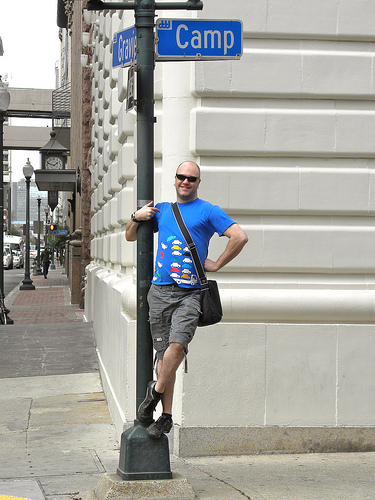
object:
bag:
[170, 202, 224, 328]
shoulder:
[192, 196, 220, 215]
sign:
[154, 18, 243, 58]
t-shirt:
[151, 197, 237, 288]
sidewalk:
[5, 257, 372, 499]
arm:
[214, 206, 249, 273]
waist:
[151, 273, 206, 295]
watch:
[131, 212, 141, 224]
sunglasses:
[176, 173, 199, 183]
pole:
[136, 0, 154, 423]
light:
[50, 224, 55, 230]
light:
[19, 157, 35, 291]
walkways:
[2, 124, 71, 149]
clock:
[44, 156, 63, 171]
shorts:
[146, 282, 202, 360]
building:
[56, 1, 375, 459]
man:
[124, 160, 248, 441]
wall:
[69, 104, 86, 310]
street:
[3, 257, 28, 296]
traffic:
[3, 227, 46, 268]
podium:
[93, 473, 197, 500]